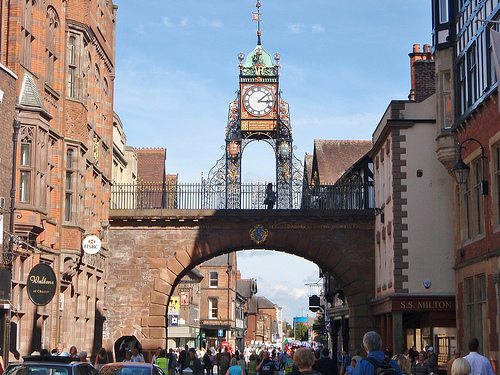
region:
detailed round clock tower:
[229, 0, 295, 158]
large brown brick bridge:
[114, 179, 389, 357]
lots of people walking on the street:
[136, 329, 386, 371]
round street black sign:
[27, 252, 71, 326]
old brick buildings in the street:
[202, 245, 304, 352]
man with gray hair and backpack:
[340, 326, 405, 371]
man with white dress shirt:
[455, 339, 494, 370]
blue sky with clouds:
[256, 253, 333, 310]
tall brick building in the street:
[66, 2, 177, 364]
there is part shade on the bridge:
[115, 187, 387, 364]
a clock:
[189, 20, 282, 148]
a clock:
[221, 48, 361, 216]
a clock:
[195, 58, 330, 173]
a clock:
[180, 13, 375, 257]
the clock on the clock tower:
[240, 74, 281, 119]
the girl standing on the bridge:
[259, 180, 280, 207]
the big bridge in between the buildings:
[117, 176, 369, 356]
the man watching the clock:
[345, 320, 398, 370]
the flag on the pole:
[246, 7, 272, 34]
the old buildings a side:
[15, 23, 116, 317]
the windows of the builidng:
[65, 143, 83, 226]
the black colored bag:
[360, 350, 396, 374]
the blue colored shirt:
[353, 358, 371, 373]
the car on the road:
[102, 357, 139, 374]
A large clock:
[207, 0, 338, 209]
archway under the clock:
[233, 133, 285, 214]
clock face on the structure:
[231, 85, 291, 126]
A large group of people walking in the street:
[188, 317, 488, 374]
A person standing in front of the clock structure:
[261, 177, 281, 207]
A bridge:
[112, 177, 394, 266]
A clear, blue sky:
[118, 0, 485, 323]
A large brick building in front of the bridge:
[0, 2, 125, 347]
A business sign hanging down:
[78, 219, 108, 265]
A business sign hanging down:
[23, 244, 67, 324]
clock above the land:
[238, 66, 300, 108]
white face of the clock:
[233, 72, 285, 129]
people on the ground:
[226, 315, 317, 374]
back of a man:
[350, 326, 415, 372]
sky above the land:
[269, 259, 305, 282]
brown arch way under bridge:
[165, 226, 367, 308]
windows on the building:
[54, 164, 106, 216]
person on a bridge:
[241, 176, 291, 218]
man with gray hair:
[353, 325, 395, 360]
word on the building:
[379, 282, 454, 331]